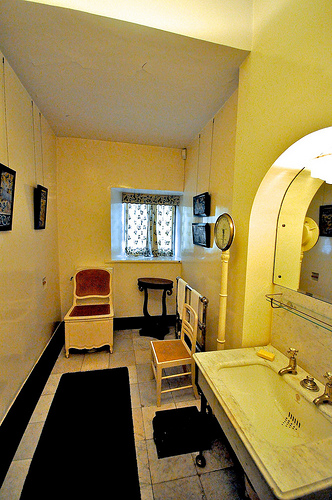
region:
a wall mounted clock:
[208, 210, 240, 262]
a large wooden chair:
[55, 248, 127, 366]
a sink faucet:
[273, 344, 302, 383]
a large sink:
[212, 363, 331, 464]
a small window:
[106, 190, 191, 270]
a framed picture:
[185, 190, 212, 218]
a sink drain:
[276, 399, 303, 435]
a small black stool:
[145, 402, 205, 464]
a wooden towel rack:
[165, 274, 209, 342]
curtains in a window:
[121, 193, 182, 261]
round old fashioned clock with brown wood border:
[213, 211, 234, 252]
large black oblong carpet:
[54, 367, 140, 498]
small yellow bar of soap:
[253, 346, 277, 364]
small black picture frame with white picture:
[32, 180, 51, 235]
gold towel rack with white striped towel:
[174, 273, 215, 320]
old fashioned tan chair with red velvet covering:
[62, 262, 121, 358]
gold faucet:
[278, 344, 301, 381]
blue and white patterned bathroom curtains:
[116, 186, 180, 266]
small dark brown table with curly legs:
[136, 269, 176, 341]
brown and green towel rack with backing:
[264, 291, 330, 329]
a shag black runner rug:
[55, 366, 139, 498]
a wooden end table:
[135, 271, 172, 337]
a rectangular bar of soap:
[254, 344, 277, 364]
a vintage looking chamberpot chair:
[62, 263, 119, 356]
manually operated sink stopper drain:
[281, 375, 311, 430]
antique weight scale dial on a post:
[212, 211, 237, 346]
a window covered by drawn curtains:
[109, 182, 184, 261]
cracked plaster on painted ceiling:
[14, 20, 184, 78]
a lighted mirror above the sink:
[268, 122, 331, 297]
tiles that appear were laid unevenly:
[146, 463, 201, 497]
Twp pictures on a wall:
[183, 187, 212, 251]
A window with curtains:
[119, 188, 180, 258]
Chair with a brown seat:
[148, 302, 200, 404]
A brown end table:
[135, 273, 174, 340]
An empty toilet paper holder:
[38, 271, 52, 298]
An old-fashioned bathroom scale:
[151, 212, 237, 459]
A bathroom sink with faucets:
[189, 319, 330, 461]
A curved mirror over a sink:
[248, 198, 328, 389]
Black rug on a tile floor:
[17, 364, 142, 498]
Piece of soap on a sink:
[254, 344, 276, 375]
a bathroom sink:
[183, 301, 330, 496]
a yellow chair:
[141, 298, 202, 410]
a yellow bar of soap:
[247, 340, 288, 374]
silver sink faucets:
[253, 340, 331, 427]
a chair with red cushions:
[57, 263, 122, 360]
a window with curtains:
[98, 181, 187, 264]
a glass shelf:
[241, 278, 330, 379]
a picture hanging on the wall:
[18, 162, 64, 247]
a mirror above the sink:
[262, 147, 329, 308]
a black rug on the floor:
[22, 354, 145, 493]